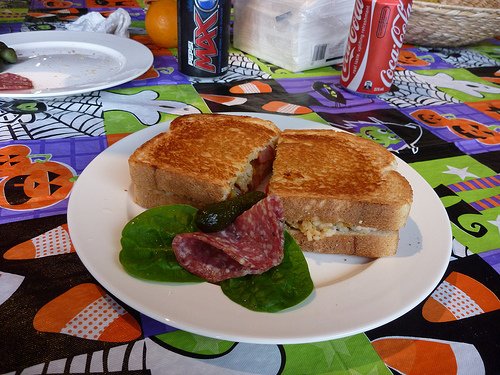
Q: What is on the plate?
A: Sandwich.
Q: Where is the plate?
A: Table.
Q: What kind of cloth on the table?
A: Halloween themed.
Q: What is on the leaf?
A: Salami and pickle.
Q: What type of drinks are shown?
A: Coca cola and pepsi.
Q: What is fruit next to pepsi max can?
A: Orange.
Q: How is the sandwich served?
A: Cut in half.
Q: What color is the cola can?
A: Red and white.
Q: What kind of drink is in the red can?
A: Coke.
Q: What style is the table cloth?
A: Halloween.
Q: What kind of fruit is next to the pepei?
A: Orange.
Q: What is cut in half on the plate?
A: Sandwich.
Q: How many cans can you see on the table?
A: 2.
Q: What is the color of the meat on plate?
A: Pink.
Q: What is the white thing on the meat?
A: Fat.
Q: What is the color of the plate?
A: White.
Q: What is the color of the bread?
A: Brown.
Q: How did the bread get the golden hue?
A: It was toasted.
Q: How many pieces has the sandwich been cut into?
A: Two.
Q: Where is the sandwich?
A: On white plate.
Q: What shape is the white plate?
A: Round.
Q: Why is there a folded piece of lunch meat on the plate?
A: For decoration.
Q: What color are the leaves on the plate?
A: Green.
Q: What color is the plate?
A: White.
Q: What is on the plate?
A: A sandwich.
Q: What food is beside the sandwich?
A: Salami.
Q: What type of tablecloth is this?
A: Holloween.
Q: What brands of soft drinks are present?
A: Coke and Pepsi.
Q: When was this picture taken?
A: Daytime.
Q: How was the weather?
A: Clear.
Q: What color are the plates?
A: White.